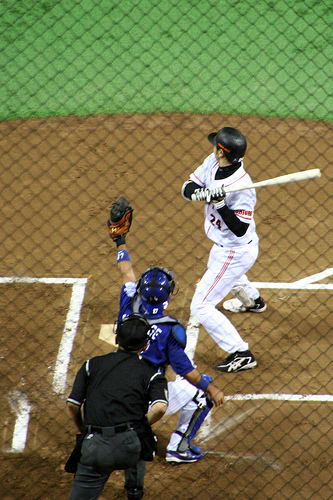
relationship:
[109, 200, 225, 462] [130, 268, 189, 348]
catcher has on gear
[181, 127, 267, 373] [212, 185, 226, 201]
batter has on gloves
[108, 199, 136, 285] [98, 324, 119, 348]
catcher behind base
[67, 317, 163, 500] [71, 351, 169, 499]
umpire has on clothing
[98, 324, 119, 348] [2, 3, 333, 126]
base on field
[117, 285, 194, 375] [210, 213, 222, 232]
jersey has a number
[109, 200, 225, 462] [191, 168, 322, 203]
catcher has a bat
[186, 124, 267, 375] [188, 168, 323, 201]
man has a bat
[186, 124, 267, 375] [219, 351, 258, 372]
man has a foot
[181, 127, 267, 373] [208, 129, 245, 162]
batter has a helmet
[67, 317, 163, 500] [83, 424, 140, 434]
umpire has a belt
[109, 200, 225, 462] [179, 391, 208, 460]
catcher has a shinguard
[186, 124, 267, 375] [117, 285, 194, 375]
man has on jersey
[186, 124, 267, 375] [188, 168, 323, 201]
man holding bat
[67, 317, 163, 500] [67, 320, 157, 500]
umpire in black